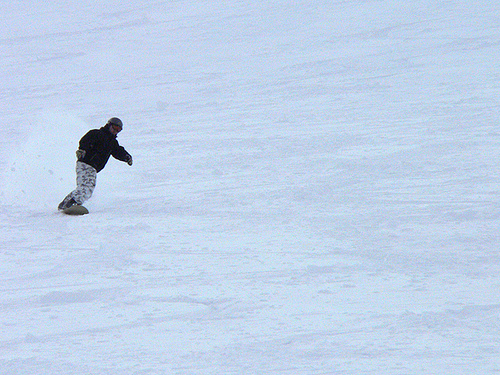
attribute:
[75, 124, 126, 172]
jacket — black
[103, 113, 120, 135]
cap — knit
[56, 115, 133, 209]
person — alone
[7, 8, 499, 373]
mountainside — snow covered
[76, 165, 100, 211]
pants — black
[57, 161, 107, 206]
pants — white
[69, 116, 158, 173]
man — young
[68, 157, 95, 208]
pants — white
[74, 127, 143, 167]
coat — black